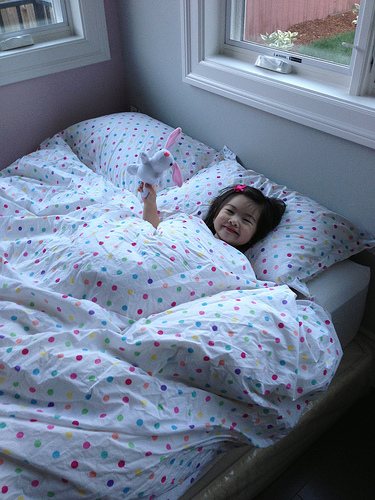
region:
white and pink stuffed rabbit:
[129, 125, 184, 204]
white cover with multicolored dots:
[1, 134, 345, 492]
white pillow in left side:
[70, 105, 221, 198]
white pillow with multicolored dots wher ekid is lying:
[158, 148, 369, 300]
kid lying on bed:
[207, 180, 285, 255]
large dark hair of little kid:
[203, 181, 283, 258]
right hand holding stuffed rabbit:
[139, 171, 167, 222]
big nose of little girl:
[228, 214, 241, 224]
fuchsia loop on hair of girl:
[234, 179, 247, 190]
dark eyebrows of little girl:
[225, 199, 258, 220]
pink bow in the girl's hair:
[232, 183, 246, 192]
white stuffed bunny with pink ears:
[125, 126, 182, 198]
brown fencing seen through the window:
[244, 1, 358, 38]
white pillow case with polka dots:
[53, 111, 219, 198]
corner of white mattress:
[293, 258, 369, 344]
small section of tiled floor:
[250, 397, 373, 499]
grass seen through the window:
[295, 30, 356, 65]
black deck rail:
[1, 0, 54, 30]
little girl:
[137, 180, 282, 251]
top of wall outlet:
[128, 105, 139, 113]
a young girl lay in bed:
[107, 122, 272, 297]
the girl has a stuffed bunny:
[125, 128, 191, 207]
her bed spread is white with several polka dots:
[16, 108, 294, 495]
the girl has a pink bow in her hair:
[232, 178, 247, 195]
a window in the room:
[217, 3, 373, 119]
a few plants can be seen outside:
[255, 4, 367, 52]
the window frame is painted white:
[182, 9, 373, 129]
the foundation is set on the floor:
[195, 279, 368, 499]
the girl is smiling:
[216, 216, 243, 244]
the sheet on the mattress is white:
[313, 263, 363, 341]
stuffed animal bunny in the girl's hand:
[113, 122, 191, 202]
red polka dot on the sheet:
[118, 375, 136, 394]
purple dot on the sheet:
[159, 381, 168, 392]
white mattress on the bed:
[324, 272, 369, 308]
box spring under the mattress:
[231, 458, 265, 489]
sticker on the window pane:
[268, 47, 302, 63]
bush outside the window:
[255, 22, 301, 50]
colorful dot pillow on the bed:
[301, 211, 330, 262]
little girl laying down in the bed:
[200, 174, 284, 253]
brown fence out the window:
[250, 6, 300, 23]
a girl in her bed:
[37, 118, 319, 381]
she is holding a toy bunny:
[115, 134, 297, 263]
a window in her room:
[227, 8, 365, 120]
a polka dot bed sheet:
[41, 149, 306, 364]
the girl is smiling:
[191, 173, 281, 266]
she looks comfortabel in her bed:
[74, 134, 298, 337]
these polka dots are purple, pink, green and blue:
[45, 220, 242, 354]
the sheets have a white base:
[8, 130, 241, 328]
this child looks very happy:
[57, 100, 333, 318]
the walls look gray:
[8, 19, 358, 221]